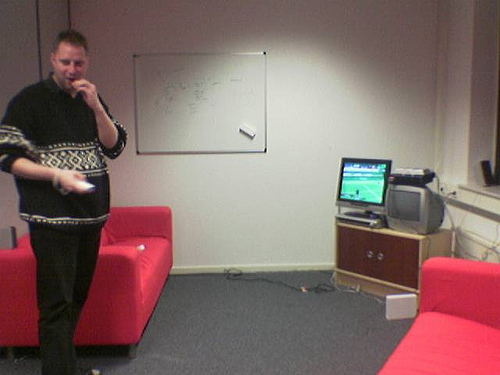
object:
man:
[0, 29, 128, 375]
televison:
[383, 184, 448, 237]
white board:
[132, 48, 269, 154]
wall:
[1, 0, 474, 277]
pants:
[27, 220, 104, 375]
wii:
[382, 293, 418, 318]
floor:
[1, 273, 418, 375]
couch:
[375, 256, 499, 373]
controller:
[73, 178, 97, 194]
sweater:
[0, 71, 130, 226]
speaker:
[480, 160, 492, 186]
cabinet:
[334, 218, 452, 304]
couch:
[0, 205, 175, 349]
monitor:
[335, 157, 393, 214]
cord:
[224, 266, 339, 295]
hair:
[51, 29, 91, 58]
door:
[372, 231, 420, 291]